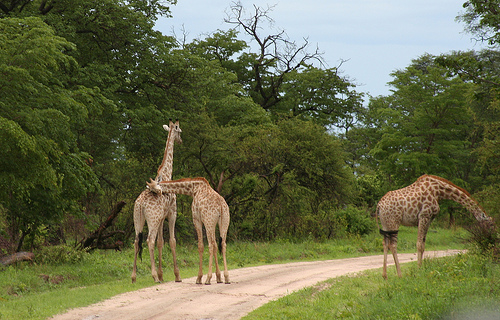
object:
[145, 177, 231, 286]
giraffe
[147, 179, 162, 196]
head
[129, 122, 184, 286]
giraffe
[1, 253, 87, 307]
grass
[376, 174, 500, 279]
giraffe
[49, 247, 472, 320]
road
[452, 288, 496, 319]
edge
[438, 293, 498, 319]
hole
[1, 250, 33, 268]
trunk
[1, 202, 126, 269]
tree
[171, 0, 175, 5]
leaf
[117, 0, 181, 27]
tree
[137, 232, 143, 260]
tip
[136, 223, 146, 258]
tail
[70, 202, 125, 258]
brush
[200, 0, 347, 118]
tree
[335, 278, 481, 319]
grass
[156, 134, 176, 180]
neck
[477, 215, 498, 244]
head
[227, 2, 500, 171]
forward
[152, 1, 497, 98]
sky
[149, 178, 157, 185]
horn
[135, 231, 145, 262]
hair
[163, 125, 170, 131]
ear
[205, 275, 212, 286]
hoof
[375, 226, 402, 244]
tail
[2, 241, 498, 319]
ground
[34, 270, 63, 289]
spot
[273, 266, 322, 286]
line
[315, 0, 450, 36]
cloud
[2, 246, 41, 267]
stump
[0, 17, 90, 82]
cluster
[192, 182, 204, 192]
spot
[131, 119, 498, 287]
cluster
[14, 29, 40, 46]
leaves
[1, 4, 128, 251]
trees